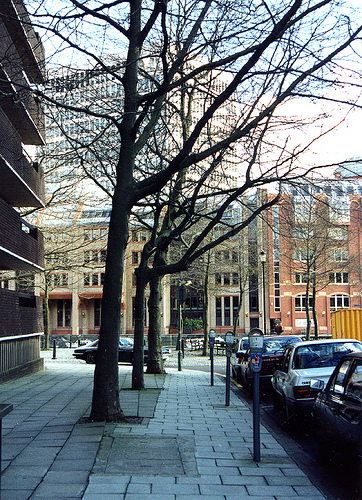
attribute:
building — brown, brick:
[240, 189, 361, 334]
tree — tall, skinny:
[200, 254, 209, 359]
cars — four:
[232, 334, 361, 423]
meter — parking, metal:
[245, 326, 267, 462]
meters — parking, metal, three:
[206, 328, 269, 459]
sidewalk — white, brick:
[167, 378, 240, 473]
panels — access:
[108, 433, 185, 475]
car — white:
[271, 341, 361, 413]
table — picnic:
[212, 334, 226, 359]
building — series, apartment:
[48, 177, 362, 342]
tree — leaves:
[84, 2, 174, 402]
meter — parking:
[244, 327, 269, 469]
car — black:
[72, 333, 169, 365]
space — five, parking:
[7, 7, 48, 360]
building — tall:
[47, 57, 245, 187]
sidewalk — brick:
[0, 363, 327, 498]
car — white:
[269, 339, 361, 425]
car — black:
[74, 337, 149, 363]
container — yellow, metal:
[330, 306, 361, 342]